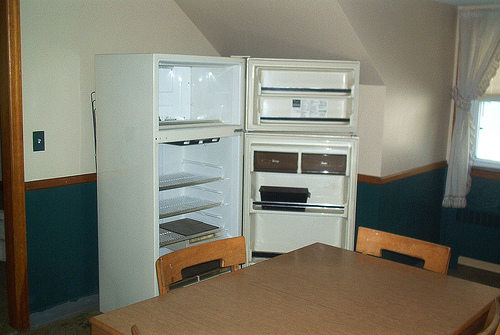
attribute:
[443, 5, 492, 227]
curtains — white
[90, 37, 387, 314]
fridge — open, kitchen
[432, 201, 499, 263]
heating vents — green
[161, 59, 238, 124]
freezer — compartment, empty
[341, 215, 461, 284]
chair — wooden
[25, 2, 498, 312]
walls — white, dark blue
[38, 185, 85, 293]
wainscoting — dark, blue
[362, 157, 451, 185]
border — wooden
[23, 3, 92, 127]
wall — white, painted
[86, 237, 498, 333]
table — wooden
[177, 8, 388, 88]
ceiling — white, slanted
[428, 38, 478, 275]
curtain — white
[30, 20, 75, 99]
wall — white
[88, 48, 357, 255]
fridge — white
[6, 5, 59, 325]
doorway — partial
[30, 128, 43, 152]
switch — wall, light, plate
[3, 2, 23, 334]
door frame — wood, brown, stained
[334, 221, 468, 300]
chair — wooden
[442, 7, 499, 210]
curtain — lacy, white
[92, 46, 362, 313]
refrigerator — empty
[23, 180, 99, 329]
green wall — painted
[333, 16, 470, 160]
wall — white, painted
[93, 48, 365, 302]
fridge — empty, white, open, door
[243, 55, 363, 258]
door — open, empty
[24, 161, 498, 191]
rail — wooden